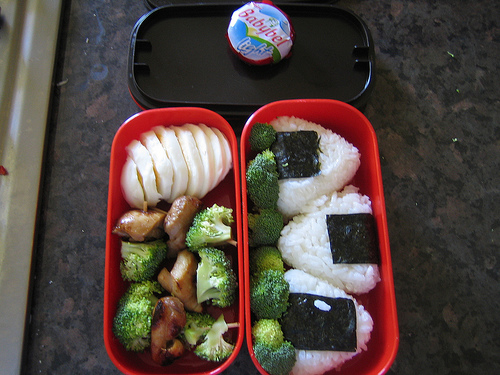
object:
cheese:
[224, 0, 298, 69]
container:
[239, 95, 402, 375]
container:
[101, 103, 246, 375]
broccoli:
[250, 317, 297, 375]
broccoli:
[250, 264, 291, 323]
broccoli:
[247, 202, 284, 251]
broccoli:
[244, 150, 283, 214]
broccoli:
[247, 118, 281, 156]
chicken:
[163, 192, 203, 259]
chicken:
[111, 201, 171, 249]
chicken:
[154, 249, 208, 318]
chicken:
[143, 294, 190, 366]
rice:
[267, 109, 365, 218]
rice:
[276, 179, 383, 294]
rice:
[278, 264, 378, 375]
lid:
[124, 0, 379, 132]